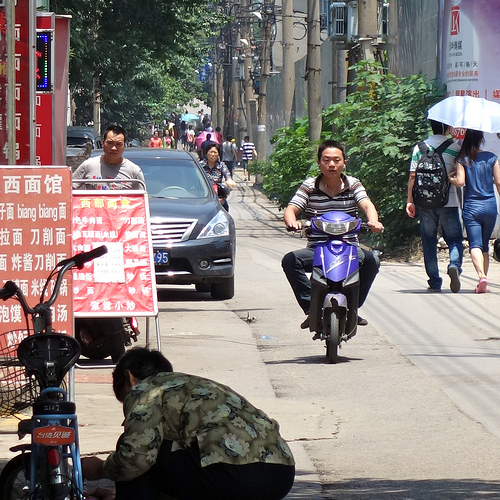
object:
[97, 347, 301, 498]
lady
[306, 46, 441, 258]
plant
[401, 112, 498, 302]
people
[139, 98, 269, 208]
people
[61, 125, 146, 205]
people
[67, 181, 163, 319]
sign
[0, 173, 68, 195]
symbols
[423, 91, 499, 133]
umbrella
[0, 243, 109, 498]
bike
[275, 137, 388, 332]
man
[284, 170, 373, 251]
shirt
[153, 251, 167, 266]
license plate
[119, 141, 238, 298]
car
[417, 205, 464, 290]
jeans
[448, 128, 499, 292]
person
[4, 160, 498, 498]
street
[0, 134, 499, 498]
ground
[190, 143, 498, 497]
road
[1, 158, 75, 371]
signs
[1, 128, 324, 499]
sidewalk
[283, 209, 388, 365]
moped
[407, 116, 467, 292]
man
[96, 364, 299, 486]
shirt